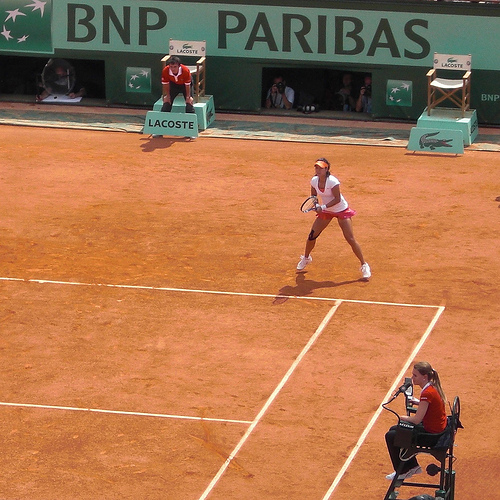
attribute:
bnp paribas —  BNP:
[56, 0, 441, 60]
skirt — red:
[315, 208, 353, 222]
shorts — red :
[315, 205, 355, 227]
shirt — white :
[311, 175, 348, 212]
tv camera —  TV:
[48, 67, 73, 91]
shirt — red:
[407, 384, 445, 436]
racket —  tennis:
[298, 195, 320, 215]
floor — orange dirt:
[3, 126, 294, 286]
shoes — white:
[279, 240, 395, 286]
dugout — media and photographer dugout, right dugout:
[262, 60, 374, 115]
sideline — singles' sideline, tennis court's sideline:
[261, 322, 363, 443]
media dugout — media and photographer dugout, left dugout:
[5, 58, 113, 99]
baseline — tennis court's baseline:
[1, 273, 445, 308]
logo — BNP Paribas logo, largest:
[0, 1, 58, 60]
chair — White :
[423, 47, 475, 113]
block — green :
[407, 99, 484, 154]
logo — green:
[3, 5, 55, 52]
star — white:
[27, 2, 49, 17]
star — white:
[4, 7, 22, 21]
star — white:
[13, 35, 33, 45]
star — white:
[1, 27, 12, 41]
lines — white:
[287, 285, 454, 343]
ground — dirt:
[152, 163, 263, 262]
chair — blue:
[131, 94, 222, 141]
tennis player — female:
[294, 158, 371, 280]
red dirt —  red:
[108, 150, 273, 240]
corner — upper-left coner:
[5, 7, 66, 93]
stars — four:
[0, 0, 50, 39]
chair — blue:
[413, 53, 479, 160]